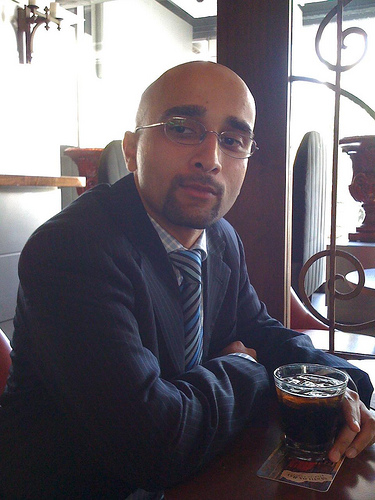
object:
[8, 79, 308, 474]
man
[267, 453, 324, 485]
coaster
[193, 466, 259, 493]
table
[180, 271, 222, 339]
tie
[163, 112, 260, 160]
glasses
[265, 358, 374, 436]
drink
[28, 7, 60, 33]
candles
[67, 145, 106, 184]
vase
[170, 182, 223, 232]
goatee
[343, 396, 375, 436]
finger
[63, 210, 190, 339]
suit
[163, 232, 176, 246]
shirt